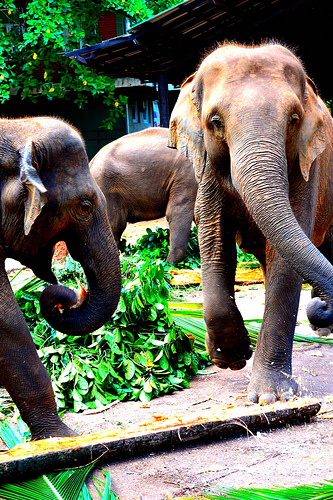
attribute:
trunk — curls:
[39, 238, 125, 338]